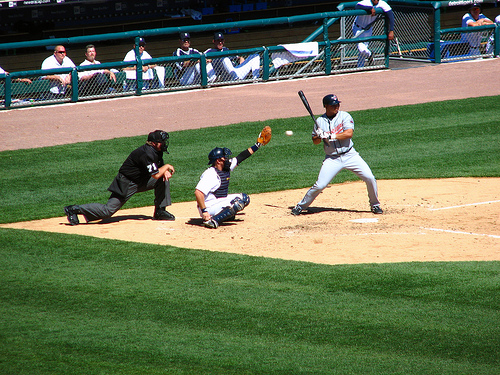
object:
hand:
[315, 128, 323, 140]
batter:
[291, 93, 384, 215]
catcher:
[194, 125, 272, 228]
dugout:
[0, 0, 500, 111]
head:
[145, 129, 170, 154]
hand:
[254, 125, 271, 149]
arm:
[194, 189, 206, 209]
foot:
[291, 203, 302, 215]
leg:
[293, 158, 344, 215]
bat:
[298, 90, 331, 147]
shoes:
[371, 204, 383, 213]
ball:
[286, 130, 293, 136]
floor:
[0, 104, 500, 305]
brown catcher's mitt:
[257, 126, 273, 146]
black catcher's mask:
[222, 160, 232, 172]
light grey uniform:
[295, 111, 381, 213]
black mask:
[160, 142, 170, 154]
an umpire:
[63, 129, 176, 225]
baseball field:
[0, 57, 499, 374]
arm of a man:
[236, 145, 259, 166]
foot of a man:
[370, 204, 383, 214]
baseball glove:
[316, 127, 337, 142]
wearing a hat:
[322, 94, 342, 108]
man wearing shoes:
[290, 206, 302, 214]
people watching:
[41, 44, 77, 94]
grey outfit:
[312, 110, 354, 157]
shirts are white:
[40, 54, 77, 94]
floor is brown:
[0, 56, 500, 153]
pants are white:
[298, 146, 380, 211]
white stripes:
[424, 227, 500, 240]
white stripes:
[387, 200, 500, 211]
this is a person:
[121, 38, 156, 91]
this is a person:
[172, 32, 216, 86]